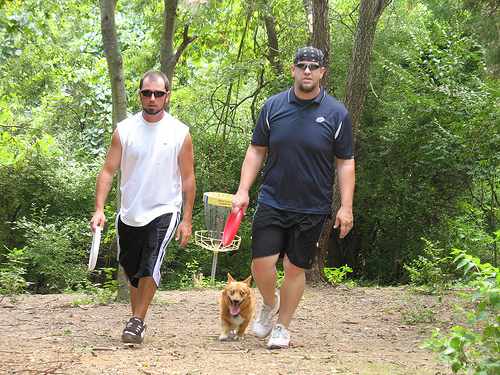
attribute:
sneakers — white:
[242, 273, 317, 363]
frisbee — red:
[223, 210, 243, 248]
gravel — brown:
[1, 287, 458, 372]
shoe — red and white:
[252, 299, 290, 349]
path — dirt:
[14, 282, 463, 362]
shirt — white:
[102, 109, 209, 223]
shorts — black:
[246, 194, 333, 264]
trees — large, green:
[324, 0, 408, 108]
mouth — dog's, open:
[227, 295, 247, 320]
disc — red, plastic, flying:
[218, 199, 249, 249]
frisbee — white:
[82, 214, 94, 278]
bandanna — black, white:
[288, 47, 326, 70]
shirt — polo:
[250, 88, 345, 213]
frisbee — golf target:
[219, 203, 243, 248]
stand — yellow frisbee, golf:
[194, 190, 251, 282]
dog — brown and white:
[202, 247, 277, 324]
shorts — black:
[252, 204, 325, 269]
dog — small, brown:
[220, 271, 250, 343]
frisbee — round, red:
[222, 207, 243, 247]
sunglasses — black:
[140, 90, 165, 96]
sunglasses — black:
[293, 63, 321, 68]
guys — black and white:
[83, 68, 196, 345]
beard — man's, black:
[145, 106, 163, 118]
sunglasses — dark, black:
[297, 60, 320, 72]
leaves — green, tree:
[405, 238, 461, 295]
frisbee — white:
[86, 225, 103, 276]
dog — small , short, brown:
[219, 273, 253, 342]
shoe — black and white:
[115, 322, 147, 346]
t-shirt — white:
[117, 112, 187, 225]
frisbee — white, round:
[72, 220, 112, 273]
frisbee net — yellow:
[194, 186, 240, 250]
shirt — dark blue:
[257, 93, 360, 226]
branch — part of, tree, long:
[347, 7, 396, 141]